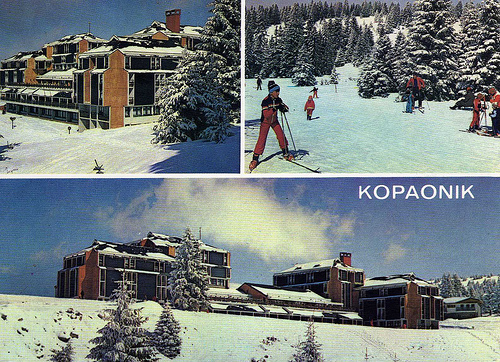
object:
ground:
[0, 291, 499, 360]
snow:
[184, 316, 393, 360]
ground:
[245, 77, 499, 173]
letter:
[356, 180, 371, 200]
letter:
[372, 183, 392, 199]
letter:
[389, 181, 407, 200]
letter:
[403, 183, 422, 201]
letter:
[418, 182, 438, 201]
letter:
[438, 181, 453, 201]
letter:
[458, 182, 477, 199]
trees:
[147, 300, 182, 361]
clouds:
[141, 176, 357, 223]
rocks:
[44, 302, 84, 342]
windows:
[124, 270, 142, 283]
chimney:
[338, 249, 353, 267]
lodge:
[56, 229, 444, 329]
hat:
[266, 76, 278, 94]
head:
[266, 79, 282, 101]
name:
[356, 180, 475, 203]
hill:
[0, 291, 484, 360]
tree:
[164, 225, 214, 315]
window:
[335, 268, 350, 280]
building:
[52, 230, 480, 330]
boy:
[248, 83, 296, 168]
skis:
[273, 151, 324, 173]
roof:
[205, 282, 350, 306]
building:
[195, 279, 367, 324]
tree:
[85, 272, 155, 362]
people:
[309, 84, 322, 97]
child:
[304, 94, 316, 119]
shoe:
[282, 150, 295, 157]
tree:
[350, 23, 493, 105]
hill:
[243, 0, 500, 176]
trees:
[290, 16, 340, 86]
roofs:
[64, 231, 231, 270]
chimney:
[162, 5, 183, 34]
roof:
[93, 19, 209, 54]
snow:
[83, 123, 136, 162]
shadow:
[147, 130, 242, 172]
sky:
[86, 185, 445, 275]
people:
[256, 72, 263, 89]